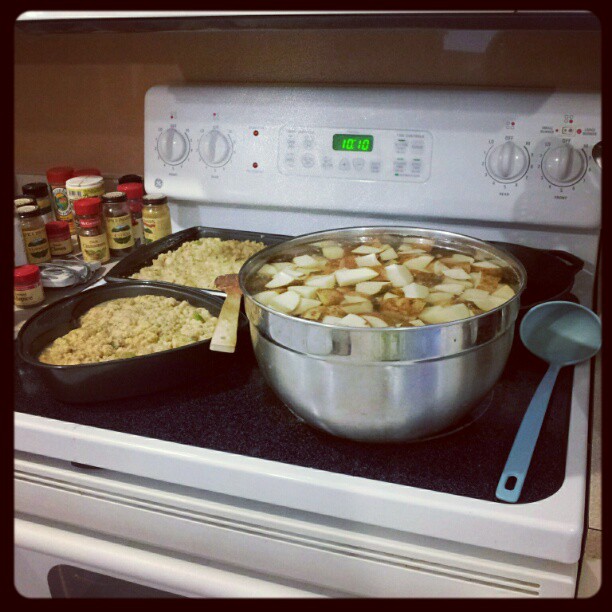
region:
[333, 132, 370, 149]
the clock on the stove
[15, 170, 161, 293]
bottles of spices on the counter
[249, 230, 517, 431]
a silver bowl on the stove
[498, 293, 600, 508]
a large blue spoon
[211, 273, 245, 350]
a wooden spoon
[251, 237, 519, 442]
a bowl of cut up potatoes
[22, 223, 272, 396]
baking dishes on the stove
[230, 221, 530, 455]
large silver bowl filled with food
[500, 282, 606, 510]
ladle laying on the stove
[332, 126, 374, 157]
digital clock on the stove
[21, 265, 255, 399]
pan on top of the stove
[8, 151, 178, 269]
a collection of spices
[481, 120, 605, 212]
two knobs on the stove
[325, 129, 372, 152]
clock indicating it's 10:10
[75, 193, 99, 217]
red cap on the spice jar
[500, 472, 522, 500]
hole in the ladle handle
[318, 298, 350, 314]
foot in the pot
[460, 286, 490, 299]
foot in the pot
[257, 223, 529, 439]
Bowl of cut up potatoes on the stove.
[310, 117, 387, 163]
Green numbers on the digital display..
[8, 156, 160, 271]
Assorted seasonings on the side of the stove.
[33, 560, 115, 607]
Black cover on the front of the oven.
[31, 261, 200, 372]
Heart shaped bowl of food on the stove.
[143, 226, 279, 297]
Pan of food on the back of stove.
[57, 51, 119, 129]
Orange tiles behind the stove.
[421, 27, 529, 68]
White sticker above the stove.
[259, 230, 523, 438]
the stainless steel bowl is filled with potatoes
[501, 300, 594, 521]
the ladle is blue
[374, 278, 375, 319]
Man holding an orange.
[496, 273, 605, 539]
ladle on the stove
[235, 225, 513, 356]
food in the pot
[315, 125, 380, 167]
clock on the stove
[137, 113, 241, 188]
a set of knobs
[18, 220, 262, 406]
a pair of pans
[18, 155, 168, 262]
a group of seasoning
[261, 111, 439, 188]
buttons on the stove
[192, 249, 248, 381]
a wooden spoon on the stove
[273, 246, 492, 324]
Food in a bowl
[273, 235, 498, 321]
Potatoes in a bowl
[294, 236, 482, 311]
Potatoes in a silver bowl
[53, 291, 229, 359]
Food in a pan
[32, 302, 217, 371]
Food in black pan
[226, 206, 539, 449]
Silver bowl on stove top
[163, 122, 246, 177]
Knobs on white oven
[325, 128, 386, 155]
Digital clock on oven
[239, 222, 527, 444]
a bowl of potatoes in water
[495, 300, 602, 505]
a plastic ladle on a stove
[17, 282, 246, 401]
a heart shaped pan on a stove